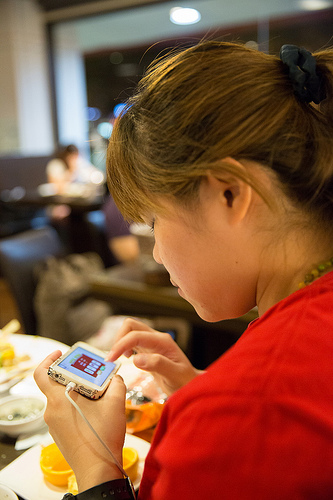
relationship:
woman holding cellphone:
[30, 34, 332, 500] [43, 336, 127, 406]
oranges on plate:
[39, 438, 140, 494] [2, 420, 154, 499]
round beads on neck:
[291, 256, 332, 298] [255, 257, 333, 324]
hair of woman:
[102, 35, 333, 232] [30, 34, 332, 500]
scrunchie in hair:
[273, 38, 326, 110] [102, 35, 333, 232]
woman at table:
[30, 34, 332, 500] [2, 361, 232, 499]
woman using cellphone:
[30, 34, 332, 500] [43, 336, 127, 406]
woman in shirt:
[30, 34, 332, 500] [130, 259, 333, 499]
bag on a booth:
[26, 251, 114, 344] [0, 208, 123, 334]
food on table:
[0, 312, 210, 499] [2, 361, 232, 499]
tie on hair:
[276, 35, 326, 106] [102, 35, 333, 232]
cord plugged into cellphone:
[61, 379, 142, 497] [43, 336, 127, 406]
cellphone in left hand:
[43, 336, 127, 406] [31, 347, 137, 473]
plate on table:
[2, 420, 154, 499] [2, 361, 232, 499]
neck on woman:
[255, 257, 333, 324] [30, 34, 332, 500]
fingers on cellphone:
[102, 313, 180, 383] [43, 336, 127, 406]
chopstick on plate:
[0, 316, 25, 343] [1, 323, 78, 429]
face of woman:
[133, 185, 254, 329] [30, 34, 332, 500]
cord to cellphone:
[61, 379, 142, 497] [43, 336, 127, 406]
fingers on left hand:
[32, 345, 74, 411] [31, 347, 137, 473]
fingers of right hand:
[102, 313, 180, 383] [107, 318, 198, 391]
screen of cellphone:
[54, 345, 115, 390] [43, 336, 127, 406]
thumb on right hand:
[133, 351, 182, 377] [107, 318, 198, 391]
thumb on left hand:
[105, 374, 132, 401] [31, 347, 137, 473]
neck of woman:
[252, 265, 331, 324] [30, 34, 332, 500]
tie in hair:
[276, 35, 326, 106] [102, 35, 333, 232]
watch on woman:
[62, 473, 136, 499] [30, 34, 332, 500]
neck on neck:
[255, 257, 333, 324] [252, 265, 331, 324]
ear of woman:
[209, 156, 259, 230] [30, 34, 332, 500]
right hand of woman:
[107, 318, 198, 391] [30, 34, 332, 500]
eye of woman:
[141, 211, 161, 237] [30, 34, 332, 500]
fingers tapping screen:
[102, 313, 180, 383] [54, 345, 115, 390]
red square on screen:
[73, 351, 109, 378] [54, 345, 115, 390]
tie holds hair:
[276, 35, 326, 106] [102, 35, 333, 232]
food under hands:
[0, 312, 210, 499] [33, 316, 201, 461]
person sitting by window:
[41, 143, 105, 189] [45, 1, 333, 177]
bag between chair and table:
[26, 251, 114, 344] [3, 211, 258, 336]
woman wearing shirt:
[30, 34, 332, 500] [130, 259, 333, 499]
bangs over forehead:
[97, 108, 165, 226] [124, 121, 160, 207]